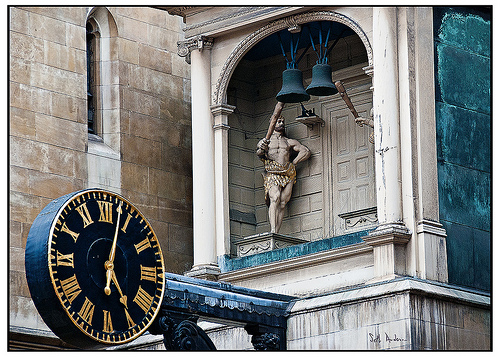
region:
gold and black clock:
[22, 185, 179, 347]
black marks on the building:
[287, 299, 410, 346]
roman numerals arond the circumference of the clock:
[32, 186, 179, 341]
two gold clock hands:
[82, 196, 165, 324]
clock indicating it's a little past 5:
[7, 186, 182, 353]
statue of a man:
[247, 106, 309, 235]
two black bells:
[272, 61, 349, 110]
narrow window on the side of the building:
[77, 6, 132, 153]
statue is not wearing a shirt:
[241, 98, 323, 240]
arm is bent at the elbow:
[283, 134, 311, 164]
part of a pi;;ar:
[373, 183, 395, 263]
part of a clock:
[111, 237, 142, 307]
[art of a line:
[394, 290, 425, 340]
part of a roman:
[134, 240, 146, 262]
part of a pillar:
[183, 151, 230, 225]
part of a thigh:
[276, 175, 304, 227]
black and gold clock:
[25, 188, 182, 353]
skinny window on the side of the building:
[75, 6, 133, 146]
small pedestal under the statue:
[236, 224, 305, 256]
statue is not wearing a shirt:
[254, 134, 312, 166]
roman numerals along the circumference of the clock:
[26, 183, 182, 343]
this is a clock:
[52, 182, 166, 355]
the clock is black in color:
[82, 237, 104, 273]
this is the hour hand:
[106, 264, 128, 304]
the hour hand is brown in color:
[106, 262, 127, 299]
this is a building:
[6, 38, 328, 184]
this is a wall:
[27, 26, 76, 141]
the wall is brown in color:
[8, 40, 62, 125]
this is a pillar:
[365, 27, 395, 199]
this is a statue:
[248, 125, 309, 244]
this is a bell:
[304, 57, 334, 98]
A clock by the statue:
[28, 188, 164, 343]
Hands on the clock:
[103, 203, 130, 310]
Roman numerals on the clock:
[30, 190, 162, 348]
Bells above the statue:
[280, 31, 335, 103]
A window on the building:
[85, 15, 105, 140]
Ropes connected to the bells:
[277, 32, 332, 64]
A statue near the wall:
[258, 100, 309, 231]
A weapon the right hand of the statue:
[262, 99, 280, 149]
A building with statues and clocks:
[9, 6, 493, 353]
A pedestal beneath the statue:
[238, 235, 305, 252]